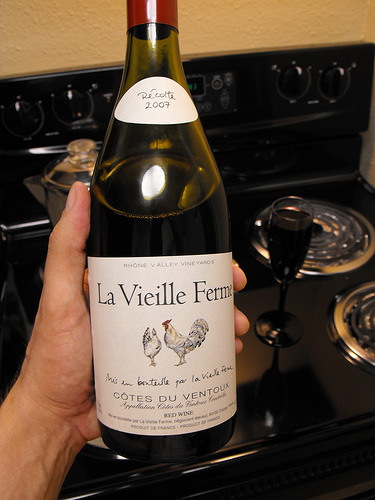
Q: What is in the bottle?
A: Wine.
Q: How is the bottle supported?
A: By someone's hand.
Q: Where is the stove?
A: Behind the bottle.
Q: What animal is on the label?
A: Chickens.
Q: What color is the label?
A: White.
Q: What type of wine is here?
A: Red wine.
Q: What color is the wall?
A: Yellow.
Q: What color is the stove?
A: Black.